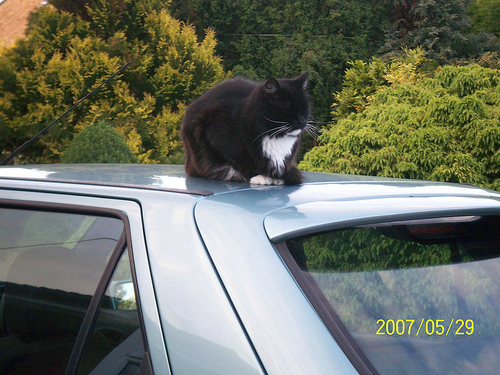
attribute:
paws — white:
[251, 175, 282, 187]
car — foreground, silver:
[0, 161, 499, 374]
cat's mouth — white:
[163, 74, 320, 193]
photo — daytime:
[6, 27, 478, 365]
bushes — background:
[368, 69, 497, 153]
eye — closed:
[268, 97, 298, 113]